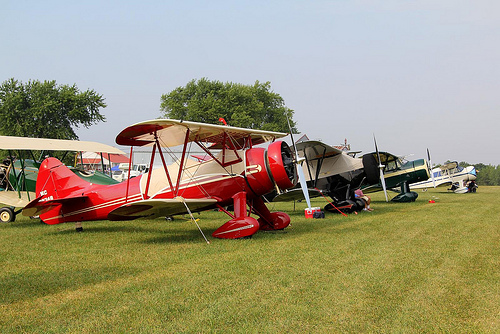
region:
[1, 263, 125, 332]
Freshly cut green grass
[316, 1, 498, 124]
Clear weather blue sky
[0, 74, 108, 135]
Leaves on a tree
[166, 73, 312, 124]
Leaves on a tree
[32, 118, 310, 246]
Red colored plane on ground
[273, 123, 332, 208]
Airplane propeller on jet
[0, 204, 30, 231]
Back wheel on airplane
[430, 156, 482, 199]
White colored airplane on ground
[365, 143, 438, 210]
Green airplane on ground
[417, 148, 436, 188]
Propellor on green airplane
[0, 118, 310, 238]
a red airplane on display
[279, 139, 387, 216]
an airplane on display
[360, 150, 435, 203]
an airplane on display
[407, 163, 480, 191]
an airplane on display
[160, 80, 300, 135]
the top of a tree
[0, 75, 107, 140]
the top of a tree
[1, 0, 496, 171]
a section of the sky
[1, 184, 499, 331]
a large grassy area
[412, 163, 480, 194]
a blue and white airplane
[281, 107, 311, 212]
the propeller on a plane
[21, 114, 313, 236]
a red and white plane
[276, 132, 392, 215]
a white and black plane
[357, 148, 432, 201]
a blue and tan plane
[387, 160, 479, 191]
a white plane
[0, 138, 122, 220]
a tan plane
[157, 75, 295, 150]
a tall green tree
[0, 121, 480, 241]
five planes lines up on a field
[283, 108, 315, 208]
propellar of a red plane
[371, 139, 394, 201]
propellar of a black and white plane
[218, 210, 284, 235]
landing gear of a red plane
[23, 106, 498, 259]
A field of airplanes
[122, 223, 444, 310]
A green grassy field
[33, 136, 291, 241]
An orange and beige plane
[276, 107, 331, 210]
A metal propeller on plane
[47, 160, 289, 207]
A gold stripe on side of plane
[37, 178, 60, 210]
White writing on tail of plane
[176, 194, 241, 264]
An anchor line from plane to ground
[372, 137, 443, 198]
A green and yellow plane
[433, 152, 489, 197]
A blue and white plane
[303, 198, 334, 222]
An orange cooler with a white top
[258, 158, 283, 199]
red propeller bi plane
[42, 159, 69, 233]
bi plane has red tail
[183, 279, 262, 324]
grass is brown and green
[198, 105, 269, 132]
green leafy tree in back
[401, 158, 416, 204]
black and gold plane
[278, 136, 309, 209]
red plane with silver propeller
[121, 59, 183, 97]
sky is gray and clear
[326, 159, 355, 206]
tan and beige plane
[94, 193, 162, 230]
red plane with white stripes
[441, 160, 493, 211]
white and blue plane